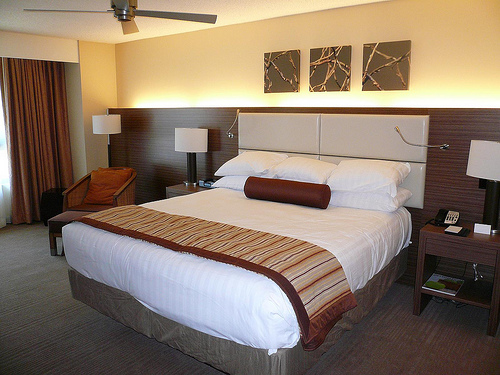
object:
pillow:
[323, 158, 413, 197]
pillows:
[83, 163, 135, 205]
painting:
[360, 37, 415, 92]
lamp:
[465, 140, 499, 233]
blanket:
[74, 202, 360, 352]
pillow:
[211, 148, 286, 178]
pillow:
[274, 154, 339, 184]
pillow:
[324, 183, 415, 214]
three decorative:
[258, 36, 412, 93]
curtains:
[0, 56, 82, 226]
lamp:
[90, 113, 121, 162]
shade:
[91, 113, 122, 138]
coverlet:
[59, 185, 413, 356]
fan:
[20, 1, 224, 37]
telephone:
[433, 205, 462, 228]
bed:
[59, 110, 436, 374]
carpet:
[0, 222, 500, 374]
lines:
[324, 338, 362, 374]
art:
[260, 49, 304, 95]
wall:
[115, 0, 500, 286]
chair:
[43, 166, 136, 256]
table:
[164, 182, 201, 202]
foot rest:
[46, 210, 99, 259]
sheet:
[59, 187, 411, 353]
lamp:
[172, 126, 209, 188]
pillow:
[241, 172, 338, 211]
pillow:
[211, 176, 249, 185]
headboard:
[234, 108, 430, 212]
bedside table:
[410, 215, 500, 337]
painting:
[305, 43, 358, 94]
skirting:
[61, 243, 414, 373]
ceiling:
[0, 0, 371, 47]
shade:
[462, 139, 500, 186]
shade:
[173, 126, 211, 158]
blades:
[132, 9, 221, 23]